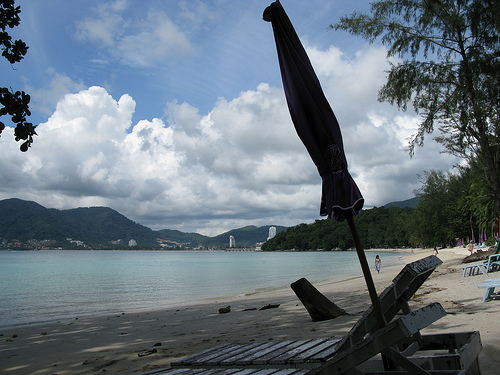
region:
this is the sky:
[66, 5, 195, 85]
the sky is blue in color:
[196, 10, 221, 92]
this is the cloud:
[80, 112, 185, 162]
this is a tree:
[396, 14, 498, 125]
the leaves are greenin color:
[397, 75, 441, 115]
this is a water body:
[86, 245, 153, 288]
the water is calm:
[86, 260, 170, 304]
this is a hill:
[43, 204, 97, 240]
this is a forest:
[372, 211, 406, 240]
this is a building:
[224, 230, 235, 252]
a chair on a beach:
[285, 226, 493, 351]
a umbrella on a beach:
[254, 32, 405, 253]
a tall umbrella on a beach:
[238, 46, 419, 268]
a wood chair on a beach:
[294, 235, 475, 359]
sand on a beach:
[148, 243, 349, 345]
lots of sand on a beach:
[174, 245, 306, 343]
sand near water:
[154, 198, 308, 335]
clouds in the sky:
[115, 115, 233, 226]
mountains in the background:
[51, 131, 201, 256]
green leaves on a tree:
[370, 183, 498, 253]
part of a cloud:
[198, 179, 238, 217]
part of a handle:
[348, 251, 390, 298]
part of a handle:
[408, 253, 423, 268]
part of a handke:
[156, 296, 196, 337]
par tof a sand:
[114, 313, 151, 345]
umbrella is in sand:
[262, 21, 386, 319]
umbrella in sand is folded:
[283, 81, 398, 323]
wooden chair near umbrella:
[175, 295, 428, 372]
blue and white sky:
[74, 59, 249, 155]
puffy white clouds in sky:
[69, 104, 297, 232]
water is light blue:
[47, 252, 262, 312]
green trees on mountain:
[22, 196, 139, 256]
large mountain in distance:
[2, 200, 211, 262]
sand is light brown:
[118, 294, 275, 353]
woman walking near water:
[374, 244, 402, 285]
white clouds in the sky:
[39, 88, 304, 195]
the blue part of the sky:
[31, 6, 246, 113]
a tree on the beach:
[356, 18, 496, 145]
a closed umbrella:
[257, 11, 369, 226]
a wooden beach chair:
[162, 264, 468, 374]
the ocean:
[8, 243, 393, 313]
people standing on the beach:
[369, 238, 449, 271]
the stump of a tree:
[292, 275, 344, 323]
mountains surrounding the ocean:
[8, 203, 289, 268]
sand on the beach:
[31, 305, 253, 359]